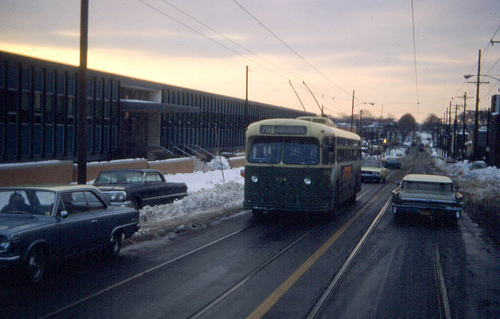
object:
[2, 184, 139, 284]
car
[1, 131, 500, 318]
street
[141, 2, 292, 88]
lines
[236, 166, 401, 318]
stripe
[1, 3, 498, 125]
sky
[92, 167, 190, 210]
car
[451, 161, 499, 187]
bank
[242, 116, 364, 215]
bus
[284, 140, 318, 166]
window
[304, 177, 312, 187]
headlight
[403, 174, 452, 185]
roof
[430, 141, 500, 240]
snow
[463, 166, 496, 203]
pile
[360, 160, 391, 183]
car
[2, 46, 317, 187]
building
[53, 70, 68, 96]
window